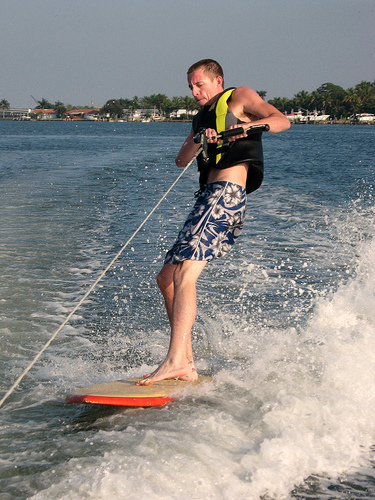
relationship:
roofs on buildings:
[28, 104, 93, 114] [31, 107, 102, 123]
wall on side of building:
[35, 112, 55, 120] [28, 108, 56, 118]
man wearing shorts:
[135, 55, 292, 390] [163, 179, 254, 271]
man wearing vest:
[135, 55, 292, 390] [186, 88, 281, 182]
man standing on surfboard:
[135, 55, 292, 390] [59, 369, 220, 419]